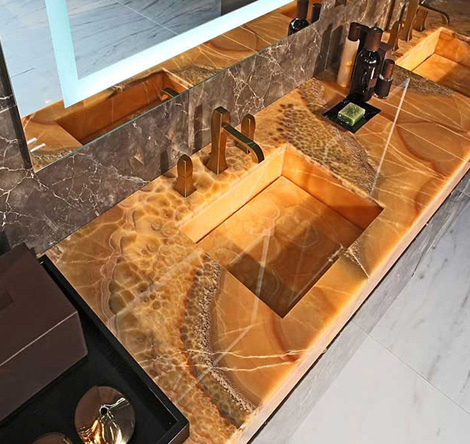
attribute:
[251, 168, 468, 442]
floor — tile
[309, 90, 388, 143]
dish — black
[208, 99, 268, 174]
faucet — on left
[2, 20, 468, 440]
counter — marble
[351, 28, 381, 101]
bottle — dark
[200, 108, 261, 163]
faucet — on right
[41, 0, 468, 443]
counter — orange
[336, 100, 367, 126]
soap — green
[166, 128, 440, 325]
sink — square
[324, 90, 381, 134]
soapdish — black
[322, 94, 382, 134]
dish — black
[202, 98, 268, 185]
faucet — brass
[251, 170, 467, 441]
tiles — white, large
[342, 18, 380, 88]
bottle — white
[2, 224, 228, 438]
tray — black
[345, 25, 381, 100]
bottle — large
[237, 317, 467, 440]
tile — white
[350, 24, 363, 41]
cap — brown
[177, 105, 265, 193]
items — circular, gold, shiny